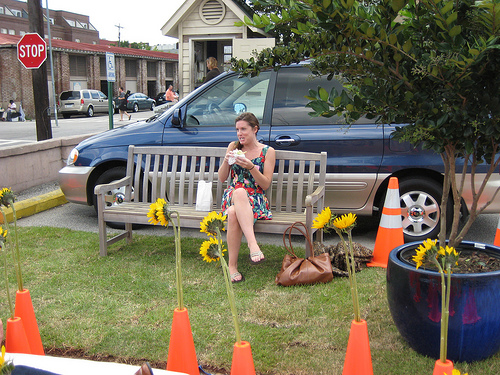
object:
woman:
[212, 109, 274, 282]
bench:
[94, 144, 333, 259]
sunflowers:
[329, 211, 360, 319]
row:
[2, 284, 460, 375]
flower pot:
[383, 239, 499, 366]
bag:
[190, 180, 216, 211]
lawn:
[0, 222, 499, 374]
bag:
[273, 221, 333, 286]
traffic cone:
[164, 308, 201, 373]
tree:
[226, 0, 498, 255]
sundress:
[218, 144, 273, 224]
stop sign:
[13, 33, 45, 72]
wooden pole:
[24, 0, 50, 143]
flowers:
[233, 176, 247, 185]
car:
[114, 91, 158, 112]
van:
[57, 49, 500, 243]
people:
[114, 87, 132, 122]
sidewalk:
[82, 106, 160, 122]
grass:
[0, 222, 499, 374]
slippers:
[249, 250, 265, 267]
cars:
[56, 89, 119, 119]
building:
[0, 0, 179, 120]